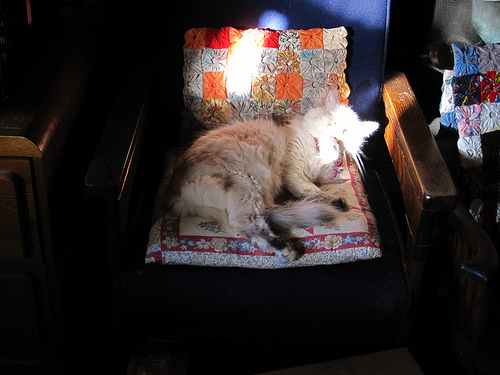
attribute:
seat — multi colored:
[160, 23, 384, 270]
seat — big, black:
[79, 0, 446, 320]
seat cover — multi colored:
[172, 26, 352, 133]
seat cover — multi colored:
[141, 130, 387, 261]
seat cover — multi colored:
[325, 223, 390, 273]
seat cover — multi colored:
[148, 232, 231, 272]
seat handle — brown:
[380, 68, 460, 245]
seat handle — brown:
[80, 81, 157, 226]